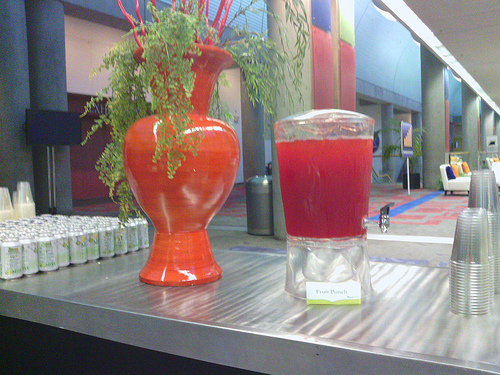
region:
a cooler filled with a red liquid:
[272, 107, 377, 305]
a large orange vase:
[121, 34, 245, 289]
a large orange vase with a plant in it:
[82, 3, 311, 292]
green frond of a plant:
[78, 3, 315, 228]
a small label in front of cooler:
[302, 278, 364, 309]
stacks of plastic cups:
[445, 165, 498, 320]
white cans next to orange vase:
[0, 208, 152, 288]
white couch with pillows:
[439, 155, 476, 196]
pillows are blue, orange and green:
[445, 158, 471, 180]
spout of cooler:
[372, 195, 395, 236]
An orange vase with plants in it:
[128, 40, 230, 285]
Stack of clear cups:
[445, 202, 492, 317]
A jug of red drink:
[273, 104, 391, 304]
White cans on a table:
[0, 215, 150, 279]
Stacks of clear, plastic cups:
[448, 163, 497, 306]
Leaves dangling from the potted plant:
[93, 13, 197, 214]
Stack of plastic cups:
[3, 179, 36, 219]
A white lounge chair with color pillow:
[442, 163, 477, 195]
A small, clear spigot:
[363, 203, 393, 233]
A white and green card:
[305, 278, 361, 304]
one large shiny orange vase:
[121, 45, 241, 285]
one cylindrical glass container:
[270, 102, 376, 309]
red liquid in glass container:
[273, 104, 372, 306]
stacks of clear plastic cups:
[447, 162, 497, 323]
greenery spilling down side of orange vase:
[95, 16, 222, 220]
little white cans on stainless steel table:
[0, 208, 148, 280]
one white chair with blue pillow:
[438, 162, 471, 199]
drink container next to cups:
[264, 91, 499, 319]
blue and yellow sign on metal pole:
[399, 119, 421, 199]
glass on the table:
[262, 84, 382, 311]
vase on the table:
[78, 5, 240, 289]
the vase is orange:
[167, 240, 200, 280]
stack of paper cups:
[447, 201, 492, 307]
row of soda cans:
[5, 211, 116, 282]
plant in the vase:
[106, 11, 221, 105]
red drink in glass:
[327, 182, 372, 207]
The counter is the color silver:
[91, 293, 438, 371]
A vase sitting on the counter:
[96, 29, 247, 288]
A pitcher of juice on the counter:
[272, 93, 407, 310]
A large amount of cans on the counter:
[0, 186, 155, 286]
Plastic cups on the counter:
[448, 155, 499, 321]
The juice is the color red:
[278, 135, 383, 238]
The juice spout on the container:
[369, 194, 401, 239]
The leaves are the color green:
[107, 25, 201, 167]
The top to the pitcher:
[267, 100, 379, 138]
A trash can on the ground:
[241, 167, 277, 242]